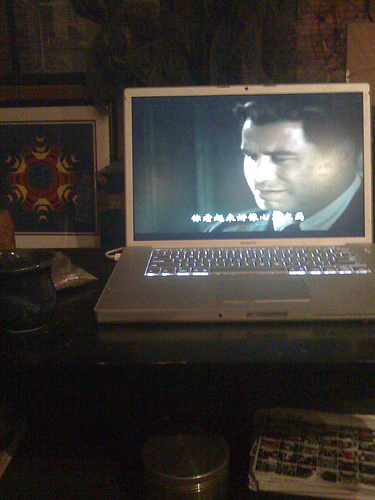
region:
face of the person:
[210, 96, 356, 216]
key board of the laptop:
[140, 219, 371, 279]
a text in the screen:
[164, 189, 327, 236]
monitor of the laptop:
[119, 81, 370, 250]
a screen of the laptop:
[119, 84, 374, 250]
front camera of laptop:
[239, 80, 252, 96]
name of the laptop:
[223, 231, 271, 247]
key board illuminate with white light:
[139, 246, 373, 281]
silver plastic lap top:
[91, 74, 373, 326]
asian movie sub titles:
[187, 207, 310, 228]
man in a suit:
[200, 96, 369, 247]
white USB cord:
[103, 241, 127, 267]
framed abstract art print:
[0, 85, 118, 262]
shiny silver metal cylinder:
[133, 418, 240, 498]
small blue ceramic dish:
[2, 243, 65, 338]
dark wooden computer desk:
[0, 225, 367, 398]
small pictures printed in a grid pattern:
[237, 392, 373, 492]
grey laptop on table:
[113, 93, 373, 348]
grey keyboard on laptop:
[137, 229, 359, 276]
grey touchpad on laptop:
[212, 273, 329, 301]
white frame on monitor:
[133, 93, 374, 255]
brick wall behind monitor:
[292, 7, 362, 74]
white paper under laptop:
[247, 401, 370, 499]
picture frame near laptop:
[6, 99, 115, 243]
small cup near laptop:
[0, 248, 70, 323]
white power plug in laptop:
[89, 238, 129, 266]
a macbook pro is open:
[87, 60, 374, 346]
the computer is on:
[88, 63, 373, 318]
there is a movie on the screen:
[110, 64, 369, 248]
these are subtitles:
[168, 194, 321, 238]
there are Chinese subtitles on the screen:
[167, 197, 320, 246]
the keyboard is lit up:
[139, 238, 372, 286]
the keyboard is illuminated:
[142, 237, 370, 280]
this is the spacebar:
[207, 264, 296, 276]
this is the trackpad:
[206, 275, 324, 303]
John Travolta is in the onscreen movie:
[219, 93, 359, 231]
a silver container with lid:
[138, 431, 228, 489]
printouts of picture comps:
[241, 411, 362, 497]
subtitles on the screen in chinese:
[178, 201, 317, 230]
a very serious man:
[229, 106, 352, 220]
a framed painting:
[12, 106, 107, 257]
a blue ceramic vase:
[3, 249, 70, 338]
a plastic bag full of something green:
[54, 251, 99, 308]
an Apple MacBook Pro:
[92, 86, 374, 322]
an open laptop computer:
[93, 81, 372, 322]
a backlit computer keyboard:
[143, 245, 369, 275]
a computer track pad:
[216, 279, 311, 301]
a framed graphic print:
[0, 85, 123, 262]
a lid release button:
[247, 311, 287, 317]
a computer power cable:
[103, 245, 122, 261]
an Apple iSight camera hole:
[244, 85, 249, 90]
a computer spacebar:
[210, 265, 285, 273]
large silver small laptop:
[93, 81, 374, 323]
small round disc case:
[139, 419, 238, 498]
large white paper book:
[245, 401, 374, 498]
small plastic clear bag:
[53, 252, 100, 288]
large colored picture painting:
[0, 0, 142, 84]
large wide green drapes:
[70, 0, 294, 102]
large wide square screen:
[130, 93, 366, 241]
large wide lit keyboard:
[145, 241, 374, 276]